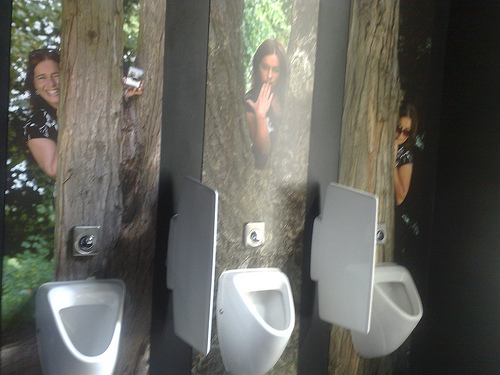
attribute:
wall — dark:
[0, 0, 447, 373]